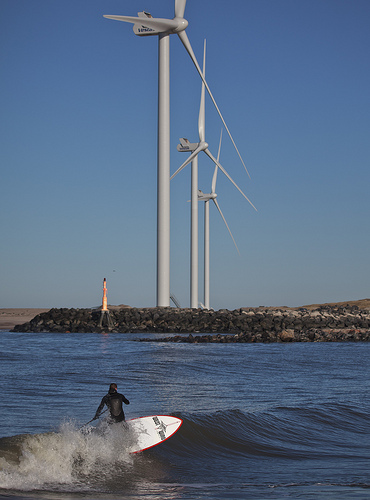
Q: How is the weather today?
A: It is cloudless.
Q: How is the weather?
A: It is cloudless.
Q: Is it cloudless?
A: Yes, it is cloudless.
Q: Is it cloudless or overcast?
A: It is cloudless.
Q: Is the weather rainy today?
A: No, it is cloudless.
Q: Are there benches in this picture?
A: No, there are no benches.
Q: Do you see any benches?
A: No, there are no benches.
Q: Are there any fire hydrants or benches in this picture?
A: No, there are no benches or fire hydrants.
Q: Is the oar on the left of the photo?
A: Yes, the oar is on the left of the image.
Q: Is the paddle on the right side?
A: No, the paddle is on the left of the image.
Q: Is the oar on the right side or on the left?
A: The oar is on the left of the image.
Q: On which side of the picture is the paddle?
A: The paddle is on the left of the image.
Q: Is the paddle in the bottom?
A: Yes, the paddle is in the bottom of the image.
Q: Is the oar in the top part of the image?
A: No, the oar is in the bottom of the image.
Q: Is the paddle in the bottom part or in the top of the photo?
A: The paddle is in the bottom of the image.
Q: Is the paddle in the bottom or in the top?
A: The paddle is in the bottom of the image.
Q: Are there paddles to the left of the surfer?
A: Yes, there is a paddle to the left of the surfer.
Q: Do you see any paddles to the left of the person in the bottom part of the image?
A: Yes, there is a paddle to the left of the surfer.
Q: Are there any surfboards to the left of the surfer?
A: No, there is a paddle to the left of the surfer.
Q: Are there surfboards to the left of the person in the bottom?
A: No, there is a paddle to the left of the surfer.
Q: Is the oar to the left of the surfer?
A: Yes, the oar is to the left of the surfer.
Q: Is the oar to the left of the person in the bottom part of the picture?
A: Yes, the oar is to the left of the surfer.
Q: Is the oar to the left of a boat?
A: No, the oar is to the left of the surfer.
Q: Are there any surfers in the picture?
A: Yes, there is a surfer.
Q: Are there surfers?
A: Yes, there is a surfer.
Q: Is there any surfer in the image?
A: Yes, there is a surfer.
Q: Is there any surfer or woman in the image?
A: Yes, there is a surfer.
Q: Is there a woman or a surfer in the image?
A: Yes, there is a surfer.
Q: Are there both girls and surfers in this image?
A: No, there is a surfer but no girls.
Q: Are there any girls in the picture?
A: No, there are no girls.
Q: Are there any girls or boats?
A: No, there are no girls or boats.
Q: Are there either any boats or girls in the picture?
A: No, there are no girls or boats.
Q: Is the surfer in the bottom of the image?
A: Yes, the surfer is in the bottom of the image.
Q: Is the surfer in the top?
A: No, the surfer is in the bottom of the image.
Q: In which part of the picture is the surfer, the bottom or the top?
A: The surfer is in the bottom of the image.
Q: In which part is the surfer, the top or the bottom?
A: The surfer is in the bottom of the image.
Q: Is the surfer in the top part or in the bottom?
A: The surfer is in the bottom of the image.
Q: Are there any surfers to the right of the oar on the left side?
A: Yes, there is a surfer to the right of the oar.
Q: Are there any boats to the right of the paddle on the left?
A: No, there is a surfer to the right of the oar.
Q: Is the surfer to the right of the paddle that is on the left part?
A: Yes, the surfer is to the right of the paddle.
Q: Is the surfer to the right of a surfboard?
A: No, the surfer is to the right of the paddle.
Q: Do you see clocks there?
A: No, there are no clocks.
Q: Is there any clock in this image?
A: No, there are no clocks.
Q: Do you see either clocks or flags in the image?
A: No, there are no clocks or flags.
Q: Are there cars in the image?
A: No, there are no cars.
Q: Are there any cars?
A: No, there are no cars.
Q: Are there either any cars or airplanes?
A: No, there are no cars or airplanes.